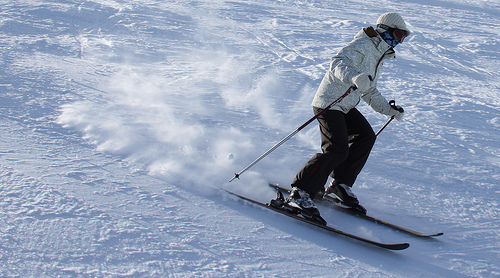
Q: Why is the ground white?
A: Snow.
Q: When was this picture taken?
A: Winter.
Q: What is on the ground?
A: Snow.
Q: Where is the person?
A: On a ski slope.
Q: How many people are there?
A: One.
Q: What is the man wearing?
A: A jacket.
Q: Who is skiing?
A: The man.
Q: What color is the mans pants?
A: Black.